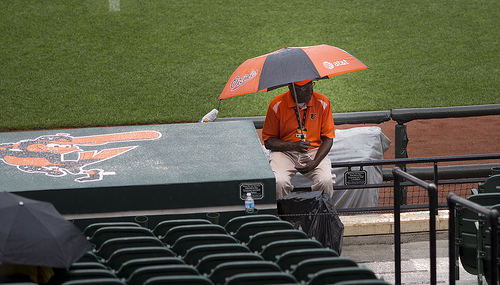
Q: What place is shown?
A: It is a stadium.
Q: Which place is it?
A: It is a stadium.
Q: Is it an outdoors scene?
A: Yes, it is outdoors.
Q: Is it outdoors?
A: Yes, it is outdoors.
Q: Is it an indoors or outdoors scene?
A: It is outdoors.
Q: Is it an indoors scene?
A: No, it is outdoors.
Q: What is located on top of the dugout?
A: The logo is on top of the dugout.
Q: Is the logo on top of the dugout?
A: Yes, the logo is on top of the dugout.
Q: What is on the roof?
A: The logo is on the roof.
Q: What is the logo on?
A: The logo is on the roof.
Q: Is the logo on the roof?
A: Yes, the logo is on the roof.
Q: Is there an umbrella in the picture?
A: Yes, there is an umbrella.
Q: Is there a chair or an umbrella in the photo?
A: Yes, there is an umbrella.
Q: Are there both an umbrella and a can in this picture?
A: No, there is an umbrella but no cans.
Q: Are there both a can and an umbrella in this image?
A: No, there is an umbrella but no cans.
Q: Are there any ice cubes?
A: No, there are no ice cubes.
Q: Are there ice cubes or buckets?
A: No, there are no ice cubes or buckets.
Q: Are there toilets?
A: No, there are no toilets.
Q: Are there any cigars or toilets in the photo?
A: No, there are no toilets or cigars.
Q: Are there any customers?
A: No, there are no customers.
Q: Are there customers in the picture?
A: No, there are no customers.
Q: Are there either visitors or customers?
A: No, there are no customers or visitors.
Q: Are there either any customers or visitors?
A: No, there are no customers or visitors.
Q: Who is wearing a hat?
A: The man is wearing a hat.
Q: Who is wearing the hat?
A: The man is wearing a hat.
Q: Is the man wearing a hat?
A: Yes, the man is wearing a hat.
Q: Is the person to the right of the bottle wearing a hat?
A: Yes, the man is wearing a hat.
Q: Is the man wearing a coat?
A: No, the man is wearing a hat.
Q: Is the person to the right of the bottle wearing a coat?
A: No, the man is wearing a hat.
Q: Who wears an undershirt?
A: The man wears an undershirt.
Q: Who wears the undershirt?
A: The man wears an undershirt.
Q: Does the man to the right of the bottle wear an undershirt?
A: Yes, the man wears an undershirt.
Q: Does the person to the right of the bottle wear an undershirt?
A: Yes, the man wears an undershirt.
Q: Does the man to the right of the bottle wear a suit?
A: No, the man wears an undershirt.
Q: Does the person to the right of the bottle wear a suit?
A: No, the man wears an undershirt.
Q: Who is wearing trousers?
A: The man is wearing trousers.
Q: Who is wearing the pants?
A: The man is wearing trousers.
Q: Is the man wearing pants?
A: Yes, the man is wearing pants.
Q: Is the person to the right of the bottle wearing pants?
A: Yes, the man is wearing pants.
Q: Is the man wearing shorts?
A: No, the man is wearing pants.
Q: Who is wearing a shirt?
A: The man is wearing a shirt.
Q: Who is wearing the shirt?
A: The man is wearing a shirt.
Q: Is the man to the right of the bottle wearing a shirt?
A: Yes, the man is wearing a shirt.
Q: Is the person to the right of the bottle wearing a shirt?
A: Yes, the man is wearing a shirt.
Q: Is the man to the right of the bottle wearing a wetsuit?
A: No, the man is wearing a shirt.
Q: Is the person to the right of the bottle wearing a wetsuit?
A: No, the man is wearing a shirt.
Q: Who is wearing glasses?
A: The man is wearing glasses.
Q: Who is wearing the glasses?
A: The man is wearing glasses.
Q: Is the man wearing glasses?
A: Yes, the man is wearing glasses.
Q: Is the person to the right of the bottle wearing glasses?
A: Yes, the man is wearing glasses.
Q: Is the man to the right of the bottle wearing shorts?
A: No, the man is wearing glasses.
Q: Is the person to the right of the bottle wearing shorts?
A: No, the man is wearing glasses.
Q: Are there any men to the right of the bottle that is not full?
A: Yes, there is a man to the right of the bottle.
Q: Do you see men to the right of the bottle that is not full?
A: Yes, there is a man to the right of the bottle.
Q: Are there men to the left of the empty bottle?
A: No, the man is to the right of the bottle.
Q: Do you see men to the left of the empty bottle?
A: No, the man is to the right of the bottle.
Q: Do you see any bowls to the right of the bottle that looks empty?
A: No, there is a man to the right of the bottle.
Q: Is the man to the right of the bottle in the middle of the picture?
A: Yes, the man is to the right of the bottle.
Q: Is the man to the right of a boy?
A: No, the man is to the right of the bottle.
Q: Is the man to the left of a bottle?
A: No, the man is to the right of a bottle.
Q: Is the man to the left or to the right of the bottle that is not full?
A: The man is to the right of the bottle.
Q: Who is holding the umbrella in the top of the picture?
A: The man is holding the umbrella.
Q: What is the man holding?
A: The man is holding the umbrella.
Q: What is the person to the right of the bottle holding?
A: The man is holding the umbrella.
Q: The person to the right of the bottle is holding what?
A: The man is holding the umbrella.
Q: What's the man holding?
A: The man is holding the umbrella.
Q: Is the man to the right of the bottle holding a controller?
A: No, the man is holding the umbrella.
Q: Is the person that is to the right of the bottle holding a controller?
A: No, the man is holding the umbrella.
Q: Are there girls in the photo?
A: No, there are no girls.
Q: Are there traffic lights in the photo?
A: No, there are no traffic lights.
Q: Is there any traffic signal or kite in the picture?
A: No, there are no traffic lights or kites.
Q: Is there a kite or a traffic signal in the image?
A: No, there are no traffic lights or kites.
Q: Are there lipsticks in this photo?
A: No, there are no lipsticks.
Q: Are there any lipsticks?
A: No, there are no lipsticks.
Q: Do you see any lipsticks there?
A: No, there are no lipsticks.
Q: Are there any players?
A: No, there are no players.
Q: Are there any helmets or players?
A: No, there are no players or helmets.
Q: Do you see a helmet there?
A: No, there are no helmets.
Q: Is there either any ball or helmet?
A: No, there are no helmets or balls.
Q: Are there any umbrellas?
A: Yes, there is an umbrella.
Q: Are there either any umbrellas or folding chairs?
A: Yes, there is an umbrella.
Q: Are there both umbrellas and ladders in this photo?
A: No, there is an umbrella but no ladders.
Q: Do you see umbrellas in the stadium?
A: Yes, there is an umbrella in the stadium.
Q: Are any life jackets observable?
A: No, there are no life jackets.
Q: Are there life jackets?
A: No, there are no life jackets.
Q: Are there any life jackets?
A: No, there are no life jackets.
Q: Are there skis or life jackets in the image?
A: No, there are no life jackets or skis.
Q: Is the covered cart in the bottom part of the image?
A: Yes, the cart is in the bottom of the image.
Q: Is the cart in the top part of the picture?
A: No, the cart is in the bottom of the image.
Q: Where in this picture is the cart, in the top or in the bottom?
A: The cart is in the bottom of the image.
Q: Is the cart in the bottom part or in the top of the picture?
A: The cart is in the bottom of the image.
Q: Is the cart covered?
A: Yes, the cart is covered.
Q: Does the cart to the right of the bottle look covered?
A: Yes, the cart is covered.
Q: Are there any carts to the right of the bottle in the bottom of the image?
A: Yes, there is a cart to the right of the bottle.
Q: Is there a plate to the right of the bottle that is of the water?
A: No, there is a cart to the right of the bottle.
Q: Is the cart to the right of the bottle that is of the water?
A: Yes, the cart is to the right of the bottle.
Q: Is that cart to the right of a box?
A: No, the cart is to the right of the bottle.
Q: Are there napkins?
A: No, there are no napkins.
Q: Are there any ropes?
A: No, there are no ropes.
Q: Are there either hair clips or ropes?
A: No, there are no ropes or hair clips.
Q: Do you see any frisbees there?
A: No, there are no frisbees.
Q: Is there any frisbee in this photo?
A: No, there are no frisbees.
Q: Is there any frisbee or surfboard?
A: No, there are no frisbees or surfboards.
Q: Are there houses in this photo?
A: No, there are no houses.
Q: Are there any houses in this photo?
A: No, there are no houses.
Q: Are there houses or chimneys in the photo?
A: No, there are no houses or chimneys.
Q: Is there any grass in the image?
A: Yes, there is grass.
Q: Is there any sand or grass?
A: Yes, there is grass.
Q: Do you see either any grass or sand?
A: Yes, there is grass.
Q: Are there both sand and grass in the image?
A: No, there is grass but no sand.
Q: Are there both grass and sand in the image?
A: No, there is grass but no sand.